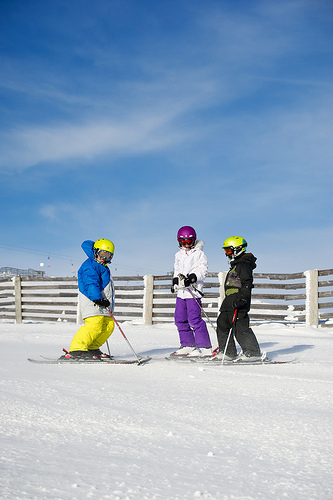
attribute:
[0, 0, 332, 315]
sky — bright blue, blue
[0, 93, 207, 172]
cloud — white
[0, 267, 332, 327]
fence — wooden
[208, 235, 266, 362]
skier — skiing, young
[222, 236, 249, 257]
helmet — yellow, green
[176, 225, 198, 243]
helmet — purple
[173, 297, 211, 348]
ski pants — purple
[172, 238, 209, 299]
jacket — white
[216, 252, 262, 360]
ski outfit — black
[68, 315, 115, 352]
pants — yellow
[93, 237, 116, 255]
helmet — yellow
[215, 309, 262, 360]
pants — black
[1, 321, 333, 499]
ground — snowy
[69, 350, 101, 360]
shoe — black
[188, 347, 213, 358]
shoe — white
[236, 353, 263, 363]
shoe — grey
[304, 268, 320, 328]
fence post — white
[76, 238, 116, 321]
jacket — blue, grey